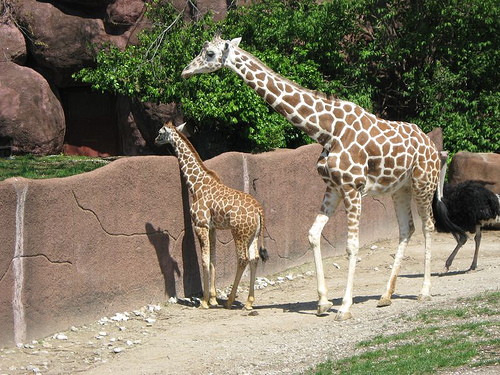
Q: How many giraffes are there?
A: Two.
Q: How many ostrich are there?
A: One.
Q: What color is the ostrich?
A: White and black.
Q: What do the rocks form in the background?
A: An opening.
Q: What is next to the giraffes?
A: A man made rock wall.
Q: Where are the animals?
A: In an enclosure.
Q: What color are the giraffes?
A: Brown and white.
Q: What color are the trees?
A: Green.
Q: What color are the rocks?
A: Reddish gray.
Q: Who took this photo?
A: A zoo visitor.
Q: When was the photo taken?
A: On a bright sunny day.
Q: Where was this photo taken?
A: At a zoo.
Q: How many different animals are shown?
A: 2.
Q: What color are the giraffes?
A: Brown and white.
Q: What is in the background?
A: Rock formation and trees.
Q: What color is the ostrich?
A: Black and white.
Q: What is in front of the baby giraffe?
A: A rock wall.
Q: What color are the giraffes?
A: Brown and white.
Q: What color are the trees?
A: Green.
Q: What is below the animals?
A: Dirt.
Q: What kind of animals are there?
A: Giraffes and ostrich.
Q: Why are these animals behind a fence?
A: They are in a zoo.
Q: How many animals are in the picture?
A: Three.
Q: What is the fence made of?
A: Stone.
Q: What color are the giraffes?
A: Brown and white.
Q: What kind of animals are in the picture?
A: Giraffes and an ostrich.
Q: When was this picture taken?
A: Daytime.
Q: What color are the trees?
A: Green.